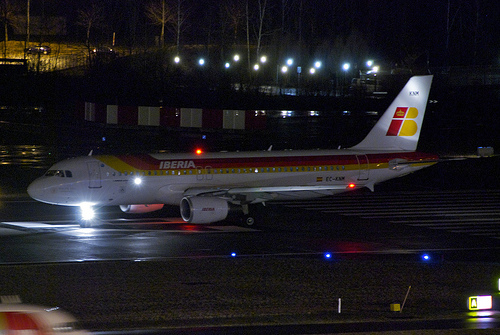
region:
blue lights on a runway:
[5, 223, 497, 292]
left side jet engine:
[178, 190, 231, 230]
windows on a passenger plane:
[107, 158, 402, 182]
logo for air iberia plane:
[384, 102, 422, 147]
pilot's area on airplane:
[31, 158, 78, 192]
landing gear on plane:
[235, 200, 258, 235]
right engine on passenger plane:
[114, 198, 161, 219]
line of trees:
[0, 4, 289, 53]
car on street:
[17, 40, 58, 61]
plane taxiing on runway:
[19, 144, 437, 230]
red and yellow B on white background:
[380, 95, 424, 150]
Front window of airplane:
[40, 161, 80, 185]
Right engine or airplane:
[173, 193, 236, 236]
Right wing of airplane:
[227, 162, 390, 212]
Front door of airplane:
[79, 158, 108, 199]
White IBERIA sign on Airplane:
[148, 156, 205, 175]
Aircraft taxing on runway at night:
[21, 68, 446, 227]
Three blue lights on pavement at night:
[226, 242, 461, 270]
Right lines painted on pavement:
[403, 186, 495, 244]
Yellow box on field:
[382, 293, 407, 318]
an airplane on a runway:
[4, 123, 456, 217]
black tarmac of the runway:
[98, 230, 202, 250]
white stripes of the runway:
[393, 175, 478, 236]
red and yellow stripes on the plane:
[241, 150, 413, 177]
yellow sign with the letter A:
[460, 293, 498, 317]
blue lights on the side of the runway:
[7, 240, 455, 272]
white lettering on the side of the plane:
[155, 158, 200, 173]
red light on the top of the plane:
[191, 143, 211, 160]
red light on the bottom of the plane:
[343, 178, 362, 194]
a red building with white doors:
[64, 88, 276, 139]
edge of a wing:
[275, 177, 293, 198]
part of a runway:
[260, 223, 294, 292]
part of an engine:
[197, 185, 217, 217]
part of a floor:
[231, 258, 247, 281]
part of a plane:
[241, 160, 257, 180]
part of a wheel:
[246, 213, 253, 222]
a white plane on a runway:
[42, 90, 441, 237]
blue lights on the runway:
[193, 237, 453, 272]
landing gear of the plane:
[236, 203, 281, 243]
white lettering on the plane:
[155, 157, 205, 171]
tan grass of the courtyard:
[153, 275, 328, 302]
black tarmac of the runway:
[262, 218, 326, 242]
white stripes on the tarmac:
[396, 180, 476, 234]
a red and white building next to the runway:
[83, 90, 319, 132]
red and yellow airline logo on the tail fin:
[385, 100, 432, 150]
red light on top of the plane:
[180, 142, 207, 163]